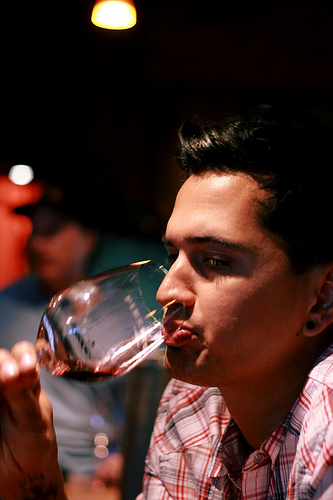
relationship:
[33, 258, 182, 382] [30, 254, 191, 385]
nearly empty glass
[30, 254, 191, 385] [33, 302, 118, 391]
glass of wine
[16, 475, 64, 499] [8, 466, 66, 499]
tattoo on wrist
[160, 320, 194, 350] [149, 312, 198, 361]
lips taking sip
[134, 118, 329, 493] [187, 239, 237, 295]
man left eye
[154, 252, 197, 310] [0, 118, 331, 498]
nose of man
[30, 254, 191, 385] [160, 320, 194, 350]
glass on mouth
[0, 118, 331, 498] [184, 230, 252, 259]
man black eyebrow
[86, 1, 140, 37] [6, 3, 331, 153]
light on ceiling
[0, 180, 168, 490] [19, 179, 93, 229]
man wearing cap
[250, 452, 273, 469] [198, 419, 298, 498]
button on collar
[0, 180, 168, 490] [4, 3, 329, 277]
man in back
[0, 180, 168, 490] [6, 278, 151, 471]
man wearing shirt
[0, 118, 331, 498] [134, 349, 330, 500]
man wearing shirt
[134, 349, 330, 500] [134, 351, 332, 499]
shirt has stripes